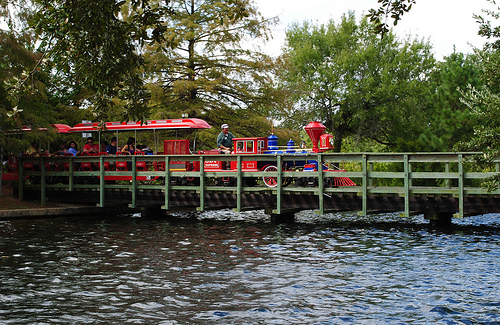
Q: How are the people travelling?
A: By train.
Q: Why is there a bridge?
A: So the train can cross over the water.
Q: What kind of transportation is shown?
A: Train.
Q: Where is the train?
A: Crossing a bridge.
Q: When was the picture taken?
A: During the daytime.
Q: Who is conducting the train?
A: Engineer.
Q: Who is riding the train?
A: Passengers.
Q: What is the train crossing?
A: River.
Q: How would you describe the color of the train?
A: Red.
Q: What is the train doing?
A: Going across the bridge.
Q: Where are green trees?
A: Against sky.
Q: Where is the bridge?
A: Across water.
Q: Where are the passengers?
A: On train ride.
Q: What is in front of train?
A: Engine compartment.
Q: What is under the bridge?
A: Clear dark water.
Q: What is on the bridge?
A: Red train.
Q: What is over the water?
A: A bridge.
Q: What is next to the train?
A: Yellow tree.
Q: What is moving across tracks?
A: A train.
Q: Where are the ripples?
A: In water.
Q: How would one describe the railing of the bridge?
A: Green and wooden.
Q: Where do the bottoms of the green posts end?
A: Above the water.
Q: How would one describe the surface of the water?
A: Small waves.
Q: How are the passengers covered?
A: Red roof.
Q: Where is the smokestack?
A: Top front of engine.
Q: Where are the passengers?
A: Passenger car behind engineer.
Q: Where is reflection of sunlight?
A: Surface of water.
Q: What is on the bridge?
A: Train engine.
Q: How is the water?
A: Calm.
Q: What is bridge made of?
A: Wood.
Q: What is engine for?
A: Train.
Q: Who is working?
A: Engineer.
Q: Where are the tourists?
A: On train.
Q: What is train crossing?
A: Water.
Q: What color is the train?
A: Red.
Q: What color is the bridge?
A: Green.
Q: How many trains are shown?
A: One.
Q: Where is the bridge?
A: Over water.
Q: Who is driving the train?
A: Conductor.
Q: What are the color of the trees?
A: Green.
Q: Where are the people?
A: On train.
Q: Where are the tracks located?
A: The bridge.